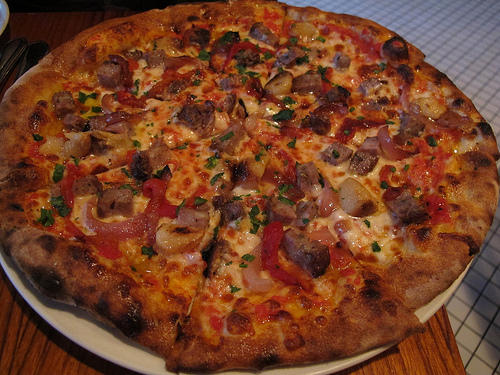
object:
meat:
[321, 142, 353, 166]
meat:
[97, 188, 134, 219]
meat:
[338, 177, 378, 217]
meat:
[172, 100, 215, 137]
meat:
[264, 70, 293, 95]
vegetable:
[143, 178, 166, 245]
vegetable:
[78, 91, 88, 104]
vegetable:
[272, 108, 295, 121]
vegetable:
[223, 42, 274, 69]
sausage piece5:
[290, 70, 321, 94]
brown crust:
[0, 235, 144, 338]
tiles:
[277, 0, 498, 375]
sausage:
[282, 228, 330, 278]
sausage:
[382, 188, 432, 227]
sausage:
[213, 178, 232, 196]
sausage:
[130, 151, 152, 182]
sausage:
[309, 111, 331, 135]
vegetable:
[82, 196, 146, 240]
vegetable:
[36, 194, 72, 227]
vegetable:
[428, 135, 437, 146]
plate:
[0, 53, 474, 375]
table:
[0, 0, 465, 375]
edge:
[0, 0, 500, 374]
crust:
[165, 304, 425, 375]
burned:
[0, 235, 150, 338]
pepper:
[261, 221, 298, 285]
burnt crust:
[259, 351, 279, 370]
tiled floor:
[275, 0, 497, 374]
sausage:
[96, 54, 129, 91]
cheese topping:
[0, 0, 500, 374]